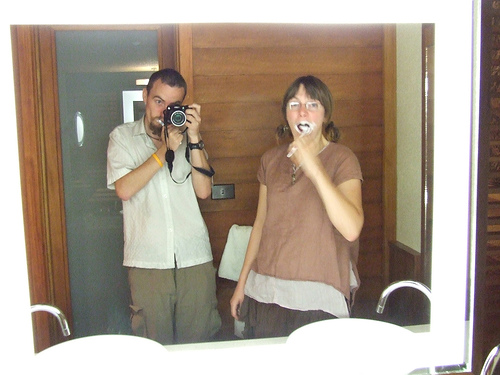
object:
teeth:
[297, 125, 310, 131]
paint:
[131, 100, 147, 123]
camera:
[161, 101, 193, 128]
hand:
[182, 103, 205, 141]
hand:
[158, 123, 183, 151]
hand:
[284, 134, 322, 172]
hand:
[226, 280, 245, 323]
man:
[105, 66, 227, 349]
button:
[164, 193, 169, 197]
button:
[159, 177, 166, 185]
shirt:
[102, 116, 217, 273]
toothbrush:
[285, 126, 309, 160]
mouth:
[294, 121, 313, 134]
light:
[74, 110, 85, 146]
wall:
[191, 24, 388, 335]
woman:
[227, 74, 367, 343]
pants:
[239, 295, 345, 345]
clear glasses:
[281, 100, 323, 110]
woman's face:
[282, 83, 327, 142]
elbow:
[338, 224, 365, 244]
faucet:
[376, 278, 433, 318]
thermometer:
[210, 183, 237, 201]